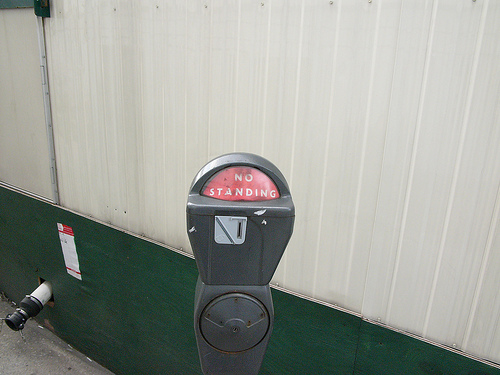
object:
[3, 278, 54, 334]
end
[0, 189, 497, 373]
board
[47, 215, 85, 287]
sticker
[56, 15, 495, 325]
panels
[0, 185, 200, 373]
lower wall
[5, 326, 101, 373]
concrete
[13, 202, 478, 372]
green board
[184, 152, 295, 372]
parking meter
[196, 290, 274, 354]
location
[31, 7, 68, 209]
pipe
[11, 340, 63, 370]
sidewalk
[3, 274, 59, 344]
pipe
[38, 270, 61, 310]
hole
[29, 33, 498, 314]
wall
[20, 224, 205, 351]
portion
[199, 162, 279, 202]
red sign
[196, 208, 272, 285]
panel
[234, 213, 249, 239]
slot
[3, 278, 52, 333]
hose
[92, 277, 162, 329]
green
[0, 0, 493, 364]
building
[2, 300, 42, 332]
black cap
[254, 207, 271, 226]
marks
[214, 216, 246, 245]
coin slot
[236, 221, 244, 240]
coin slot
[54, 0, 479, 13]
screws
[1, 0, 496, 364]
siding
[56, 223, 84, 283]
sign